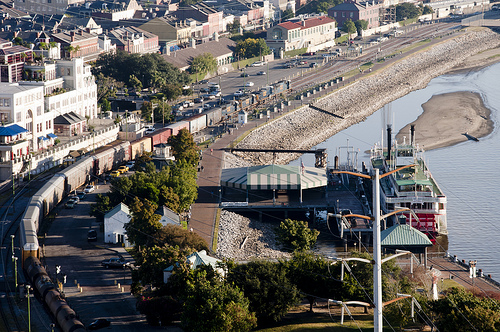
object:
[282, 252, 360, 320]
tree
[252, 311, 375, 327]
shadow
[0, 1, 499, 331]
photo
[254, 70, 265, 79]
car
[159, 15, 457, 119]
street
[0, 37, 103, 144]
building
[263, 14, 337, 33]
roof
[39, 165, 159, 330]
road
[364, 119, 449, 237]
ferry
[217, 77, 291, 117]
train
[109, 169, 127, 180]
car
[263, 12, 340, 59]
house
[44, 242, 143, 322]
parking lot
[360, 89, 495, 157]
island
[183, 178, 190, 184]
leaf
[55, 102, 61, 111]
window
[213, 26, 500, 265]
gravel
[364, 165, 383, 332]
pole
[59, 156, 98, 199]
compartment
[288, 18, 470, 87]
train track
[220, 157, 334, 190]
roof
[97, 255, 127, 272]
car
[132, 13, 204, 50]
house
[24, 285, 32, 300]
tower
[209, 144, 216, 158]
person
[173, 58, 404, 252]
walkway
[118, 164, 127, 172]
taxi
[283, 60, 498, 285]
lake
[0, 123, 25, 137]
awning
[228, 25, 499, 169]
sand bar